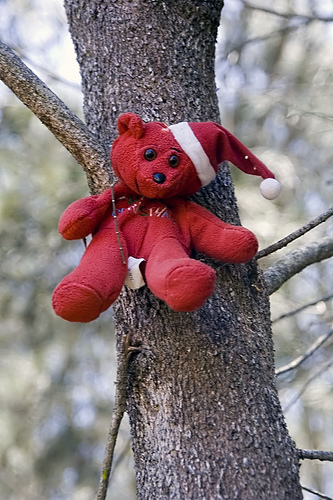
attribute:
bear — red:
[48, 108, 283, 322]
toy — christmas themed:
[72, 122, 221, 285]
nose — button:
[151, 170, 166, 184]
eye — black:
[142, 146, 161, 166]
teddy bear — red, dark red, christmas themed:
[50, 114, 282, 324]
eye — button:
[166, 154, 181, 166]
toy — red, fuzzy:
[51, 111, 283, 324]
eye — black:
[168, 154, 177, 166]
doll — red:
[45, 115, 279, 339]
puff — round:
[258, 177, 286, 198]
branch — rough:
[0, 40, 109, 186]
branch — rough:
[293, 448, 332, 460]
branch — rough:
[254, 206, 331, 259]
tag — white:
[124, 252, 151, 294]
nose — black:
[151, 172, 164, 182]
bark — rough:
[62, 36, 295, 492]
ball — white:
[259, 176, 281, 201]